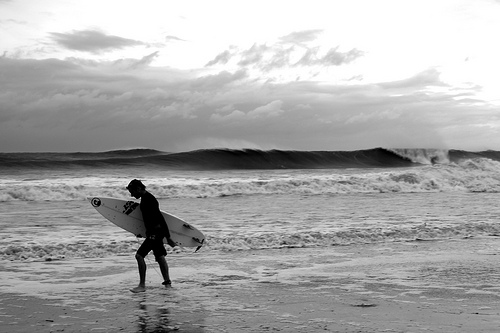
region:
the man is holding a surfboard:
[73, 163, 213, 316]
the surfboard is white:
[72, 182, 221, 247]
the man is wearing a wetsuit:
[118, 178, 190, 280]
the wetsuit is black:
[128, 196, 178, 257]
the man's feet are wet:
[114, 268, 196, 306]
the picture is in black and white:
[2, 0, 493, 322]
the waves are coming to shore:
[4, 171, 495, 268]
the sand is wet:
[0, 281, 495, 331]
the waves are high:
[201, 131, 496, 184]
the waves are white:
[32, 173, 411, 215]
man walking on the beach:
[79, 166, 222, 298]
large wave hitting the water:
[329, 124, 486, 188]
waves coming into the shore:
[207, 162, 451, 311]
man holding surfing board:
[87, 172, 217, 304]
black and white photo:
[26, 114, 300, 304]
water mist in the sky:
[154, 114, 294, 164]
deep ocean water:
[286, 145, 425, 207]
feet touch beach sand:
[117, 264, 209, 311]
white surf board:
[86, 187, 223, 268]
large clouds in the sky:
[54, 10, 374, 127]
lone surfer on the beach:
[81, 173, 213, 305]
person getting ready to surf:
[86, 174, 220, 305]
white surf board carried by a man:
[87, 192, 219, 257]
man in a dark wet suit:
[124, 178, 180, 307]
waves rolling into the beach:
[134, 137, 487, 199]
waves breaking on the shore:
[250, 167, 462, 199]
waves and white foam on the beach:
[255, 256, 484, 331]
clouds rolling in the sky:
[55, 12, 290, 117]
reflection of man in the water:
[131, 292, 197, 328]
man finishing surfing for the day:
[75, 158, 215, 301]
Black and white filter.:
[4, 2, 496, 329]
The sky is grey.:
[3, 2, 486, 162]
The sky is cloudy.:
[4, 1, 494, 152]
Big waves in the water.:
[3, 140, 498, 183]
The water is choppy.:
[2, 137, 499, 272]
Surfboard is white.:
[84, 186, 207, 252]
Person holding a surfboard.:
[88, 172, 203, 287]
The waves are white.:
[4, 151, 498, 216]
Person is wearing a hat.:
[117, 173, 150, 197]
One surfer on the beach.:
[75, 163, 208, 293]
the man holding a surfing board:
[62, 117, 312, 332]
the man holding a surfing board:
[86, 141, 212, 323]